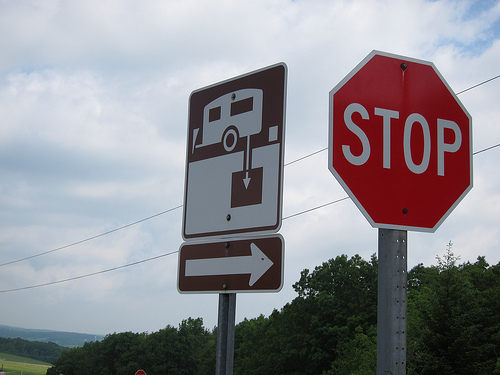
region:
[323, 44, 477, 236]
a red octagonal stop sign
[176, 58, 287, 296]
a brown trailer dump sign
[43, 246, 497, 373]
the trees behind the signs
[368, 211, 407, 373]
a metal pole holding the stop sign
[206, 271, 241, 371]
a metal pole holding the brown trailer sign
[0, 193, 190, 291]
wires overhead behind the poles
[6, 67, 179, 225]
a cloud in the sky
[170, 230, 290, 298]
an arrow sign pointing to the right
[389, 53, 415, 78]
a bolt holding the sign to the pole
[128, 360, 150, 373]
another stop sign in the distance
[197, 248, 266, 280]
white arrow on a street sign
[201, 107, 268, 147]
picture of a camper on a street sign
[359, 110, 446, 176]
STOP is written on a street sign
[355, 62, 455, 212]
street sign is red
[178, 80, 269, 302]
two street signs that are black and white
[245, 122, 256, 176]
arrow coming out of the camper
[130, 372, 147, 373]
red street sign by the trees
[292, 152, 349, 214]
power lines behind the street signs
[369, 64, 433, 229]
STOP sign is a octagon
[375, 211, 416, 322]
STOP is on a pole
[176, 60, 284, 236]
brown and white street sign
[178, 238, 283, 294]
brown and white arrow sign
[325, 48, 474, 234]
red and white street sign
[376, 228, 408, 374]
grey metal stop sign pole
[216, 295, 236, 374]
grey metal sign pole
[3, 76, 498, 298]
black rubber electrical wires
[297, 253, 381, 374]
tree with green leaves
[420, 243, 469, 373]
evergreen tree by road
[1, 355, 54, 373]
green field by trees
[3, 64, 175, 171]
white cloud in sky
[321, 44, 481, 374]
red stop sign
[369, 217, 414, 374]
metal post holding up the stop sign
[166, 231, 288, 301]
brown sign with a white arrow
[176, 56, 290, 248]
sign indicating a septic tank nearby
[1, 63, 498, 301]
two power lines in the background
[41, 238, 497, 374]
tops of several trees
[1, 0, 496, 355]
mostly cloudy sky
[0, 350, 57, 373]
a green field in the background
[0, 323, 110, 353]
mountains in the distance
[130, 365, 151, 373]
the top of a stop sign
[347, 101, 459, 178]
the word stop on the sign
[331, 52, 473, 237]
the stop sign on the pole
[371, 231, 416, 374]
the pole of the stop sign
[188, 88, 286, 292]
the brown camping sign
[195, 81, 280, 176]
the camper on the sign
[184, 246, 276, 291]
the arrow on the sign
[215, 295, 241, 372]
the pole that the camper sign is on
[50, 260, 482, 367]
trees lined up behind the signs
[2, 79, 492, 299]
the powerlines behind the sign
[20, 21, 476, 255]
the clouds in the sky